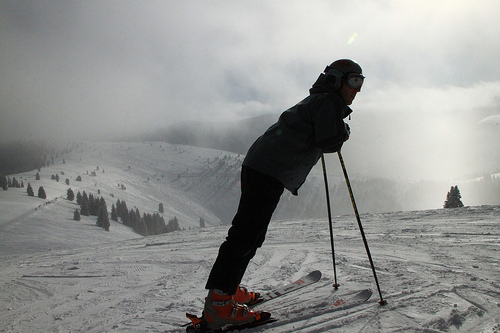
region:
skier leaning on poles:
[197, 54, 404, 325]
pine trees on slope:
[51, 184, 165, 233]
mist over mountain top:
[159, 98, 231, 158]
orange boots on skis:
[204, 275, 269, 331]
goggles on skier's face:
[340, 72, 372, 95]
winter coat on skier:
[244, 93, 349, 196]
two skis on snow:
[274, 267, 377, 319]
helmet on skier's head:
[328, 53, 367, 76]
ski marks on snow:
[34, 256, 151, 309]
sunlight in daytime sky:
[392, 3, 472, 55]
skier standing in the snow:
[173, 37, 415, 329]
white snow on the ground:
[5, 245, 170, 320]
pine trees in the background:
[440, 176, 470, 216]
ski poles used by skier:
[315, 162, 387, 317]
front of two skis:
[285, 260, 377, 315]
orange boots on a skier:
[193, 278, 276, 328]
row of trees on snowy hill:
[66, 182, 200, 234]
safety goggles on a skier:
[344, 69, 369, 92]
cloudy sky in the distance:
[24, 11, 251, 114]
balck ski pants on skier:
[192, 168, 273, 288]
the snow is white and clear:
[37, 157, 161, 278]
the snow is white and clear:
[43, 206, 163, 325]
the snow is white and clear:
[79, 138, 219, 325]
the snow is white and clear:
[69, 196, 154, 262]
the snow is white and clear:
[11, 173, 117, 310]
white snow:
[72, 265, 159, 329]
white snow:
[110, 255, 165, 322]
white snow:
[81, 251, 151, 306]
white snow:
[117, 287, 174, 319]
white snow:
[95, 302, 140, 323]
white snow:
[94, 281, 185, 325]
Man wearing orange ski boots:
[195, 261, 270, 323]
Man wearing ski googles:
[337, 65, 372, 90]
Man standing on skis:
[171, 248, 378, 320]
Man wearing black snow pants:
[198, 159, 286, 291]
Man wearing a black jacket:
[235, 85, 375, 172]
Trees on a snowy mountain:
[67, 187, 169, 238]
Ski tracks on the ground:
[63, 253, 185, 291]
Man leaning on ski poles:
[291, 110, 403, 310]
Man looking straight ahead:
[321, 63, 371, 104]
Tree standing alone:
[442, 180, 464, 222]